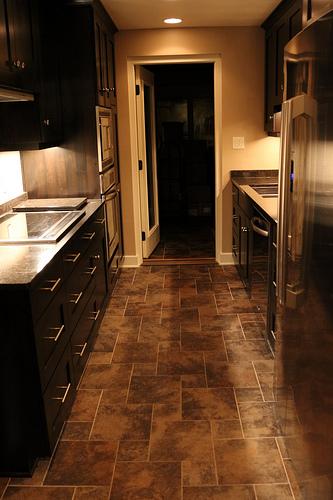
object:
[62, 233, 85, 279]
drawers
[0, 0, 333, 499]
kitchen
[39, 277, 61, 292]
handle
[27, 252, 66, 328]
drawer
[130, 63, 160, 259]
door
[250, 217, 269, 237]
handle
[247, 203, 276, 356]
appliance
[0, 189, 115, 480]
counter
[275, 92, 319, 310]
handle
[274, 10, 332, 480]
refrigerator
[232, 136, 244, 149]
power square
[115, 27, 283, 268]
wall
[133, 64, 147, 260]
hinge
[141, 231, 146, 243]
lower hinge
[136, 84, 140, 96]
upper hinge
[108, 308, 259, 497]
floor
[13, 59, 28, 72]
handles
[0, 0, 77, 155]
cabinets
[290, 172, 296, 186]
light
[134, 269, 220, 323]
tiles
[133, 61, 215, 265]
doorway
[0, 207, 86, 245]
range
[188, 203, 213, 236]
boxes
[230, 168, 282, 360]
counter